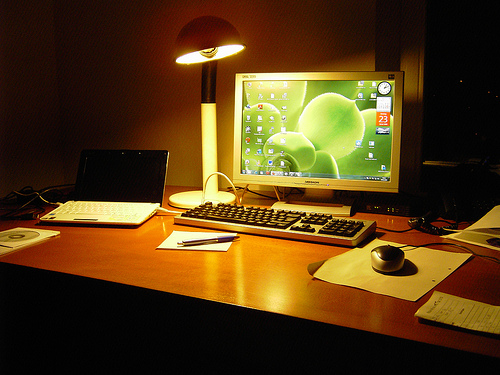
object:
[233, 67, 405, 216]
desktop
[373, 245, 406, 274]
mouse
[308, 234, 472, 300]
paper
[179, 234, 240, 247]
pen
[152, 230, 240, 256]
notebook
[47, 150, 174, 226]
laptop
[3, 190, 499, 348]
desk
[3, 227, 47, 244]
cd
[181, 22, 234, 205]
lamp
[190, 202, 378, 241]
keyboard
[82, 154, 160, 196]
screen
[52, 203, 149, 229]
keyboard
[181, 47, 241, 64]
light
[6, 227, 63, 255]
white case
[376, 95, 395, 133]
calender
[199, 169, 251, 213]
wire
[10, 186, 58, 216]
cords